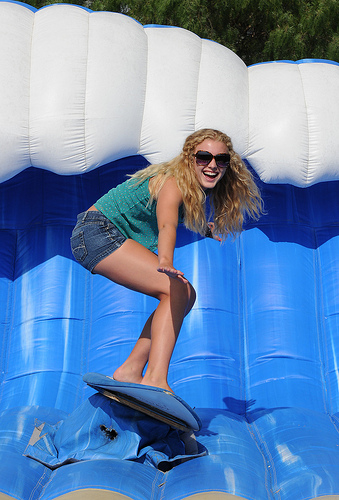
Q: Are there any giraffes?
A: No, there are no giraffes.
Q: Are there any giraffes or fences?
A: No, there are no giraffes or fences.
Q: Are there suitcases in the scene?
A: No, there are no suitcases.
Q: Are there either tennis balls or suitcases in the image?
A: No, there are no suitcases or tennis balls.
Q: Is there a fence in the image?
A: No, there are no fences.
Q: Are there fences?
A: No, there are no fences.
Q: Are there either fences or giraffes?
A: No, there are no fences or giraffes.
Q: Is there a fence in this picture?
A: No, there are no fences.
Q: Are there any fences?
A: No, there are no fences.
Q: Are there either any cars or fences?
A: No, there are no fences or cars.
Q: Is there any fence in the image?
A: No, there are no fences.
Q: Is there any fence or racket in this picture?
A: No, there are no fences or rackets.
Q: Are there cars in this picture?
A: No, there are no cars.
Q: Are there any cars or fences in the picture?
A: No, there are no cars or fences.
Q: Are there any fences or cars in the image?
A: No, there are no cars or fences.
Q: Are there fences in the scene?
A: No, there are no fences.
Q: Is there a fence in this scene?
A: No, there are no fences.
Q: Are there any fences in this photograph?
A: No, there are no fences.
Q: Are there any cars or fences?
A: No, there are no fences or cars.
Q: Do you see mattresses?
A: No, there are no mattresses.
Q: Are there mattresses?
A: No, there are no mattresses.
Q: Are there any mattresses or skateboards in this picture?
A: No, there are no mattresses or skateboards.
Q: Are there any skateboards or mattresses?
A: No, there are no mattresses or skateboards.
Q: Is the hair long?
A: Yes, the hair is long.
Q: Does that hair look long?
A: Yes, the hair is long.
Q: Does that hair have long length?
A: Yes, the hair is long.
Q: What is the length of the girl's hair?
A: The hair is long.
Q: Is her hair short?
A: No, the hair is long.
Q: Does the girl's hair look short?
A: No, the hair is long.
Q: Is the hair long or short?
A: The hair is long.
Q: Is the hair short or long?
A: The hair is long.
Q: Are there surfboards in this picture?
A: Yes, there is a surfboard.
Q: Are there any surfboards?
A: Yes, there is a surfboard.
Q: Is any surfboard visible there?
A: Yes, there is a surfboard.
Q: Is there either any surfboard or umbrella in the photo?
A: Yes, there is a surfboard.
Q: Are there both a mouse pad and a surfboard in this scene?
A: No, there is a surfboard but no mouse pads.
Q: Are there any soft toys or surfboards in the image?
A: Yes, there is a soft surfboard.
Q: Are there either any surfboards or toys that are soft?
A: Yes, the surfboard is soft.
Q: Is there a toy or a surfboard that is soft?
A: Yes, the surfboard is soft.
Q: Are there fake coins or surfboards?
A: Yes, there is a fake surfboard.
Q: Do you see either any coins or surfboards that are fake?
A: Yes, the surfboard is fake.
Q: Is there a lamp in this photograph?
A: No, there are no lamps.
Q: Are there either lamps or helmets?
A: No, there are no lamps or helmets.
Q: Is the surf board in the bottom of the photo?
A: Yes, the surf board is in the bottom of the image.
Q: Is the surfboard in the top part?
A: No, the surfboard is in the bottom of the image.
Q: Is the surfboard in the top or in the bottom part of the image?
A: The surfboard is in the bottom of the image.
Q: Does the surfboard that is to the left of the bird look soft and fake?
A: Yes, the surfboard is soft and fake.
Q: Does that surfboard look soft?
A: Yes, the surfboard is soft.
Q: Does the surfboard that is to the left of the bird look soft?
A: Yes, the surfboard is soft.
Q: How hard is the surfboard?
A: The surfboard is soft.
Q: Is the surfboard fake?
A: Yes, the surfboard is fake.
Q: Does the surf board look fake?
A: Yes, the surf board is fake.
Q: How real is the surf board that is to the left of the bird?
A: The surfboard is fake.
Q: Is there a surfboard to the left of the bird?
A: Yes, there is a surfboard to the left of the bird.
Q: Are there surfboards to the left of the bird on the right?
A: Yes, there is a surfboard to the left of the bird.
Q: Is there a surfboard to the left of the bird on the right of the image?
A: Yes, there is a surfboard to the left of the bird.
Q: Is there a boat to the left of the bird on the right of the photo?
A: No, there is a surfboard to the left of the bird.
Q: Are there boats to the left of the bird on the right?
A: No, there is a surfboard to the left of the bird.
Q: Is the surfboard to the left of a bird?
A: Yes, the surfboard is to the left of a bird.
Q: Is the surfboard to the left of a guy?
A: No, the surfboard is to the left of a bird.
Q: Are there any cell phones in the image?
A: No, there are no cell phones.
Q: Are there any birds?
A: Yes, there is a bird.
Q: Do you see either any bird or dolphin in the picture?
A: Yes, there is a bird.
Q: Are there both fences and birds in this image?
A: No, there is a bird but no fences.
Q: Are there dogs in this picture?
A: No, there are no dogs.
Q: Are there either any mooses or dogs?
A: No, there are no dogs or mooses.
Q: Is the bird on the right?
A: Yes, the bird is on the right of the image.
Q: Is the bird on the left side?
A: No, the bird is on the right of the image.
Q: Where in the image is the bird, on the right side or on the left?
A: The bird is on the right of the image.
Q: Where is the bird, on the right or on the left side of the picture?
A: The bird is on the right of the image.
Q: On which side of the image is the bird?
A: The bird is on the right of the image.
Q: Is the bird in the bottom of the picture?
A: Yes, the bird is in the bottom of the image.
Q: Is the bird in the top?
A: No, the bird is in the bottom of the image.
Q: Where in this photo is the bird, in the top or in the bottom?
A: The bird is in the bottom of the image.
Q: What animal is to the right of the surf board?
A: The animal is a bird.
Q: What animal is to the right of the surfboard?
A: The animal is a bird.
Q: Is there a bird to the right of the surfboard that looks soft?
A: Yes, there is a bird to the right of the surfboard.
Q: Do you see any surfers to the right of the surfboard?
A: No, there is a bird to the right of the surfboard.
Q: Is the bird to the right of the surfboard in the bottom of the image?
A: Yes, the bird is to the right of the surfboard.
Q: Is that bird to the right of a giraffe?
A: No, the bird is to the right of the surfboard.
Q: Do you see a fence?
A: No, there are no fences.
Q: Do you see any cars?
A: No, there are no cars.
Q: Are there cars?
A: No, there are no cars.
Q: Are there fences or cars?
A: No, there are no cars or fences.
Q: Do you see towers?
A: No, there are no towers.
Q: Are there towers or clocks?
A: No, there are no towers or clocks.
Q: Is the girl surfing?
A: Yes, the girl is surfing.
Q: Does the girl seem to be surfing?
A: Yes, the girl is surfing.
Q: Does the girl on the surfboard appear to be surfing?
A: Yes, the girl is surfing.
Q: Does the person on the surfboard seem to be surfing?
A: Yes, the girl is surfing.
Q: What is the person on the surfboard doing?
A: The girl is surfing.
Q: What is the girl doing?
A: The girl is surfing.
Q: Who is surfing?
A: The girl is surfing.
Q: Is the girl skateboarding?
A: No, the girl is surfing.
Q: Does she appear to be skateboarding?
A: No, the girl is surfing.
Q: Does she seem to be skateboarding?
A: No, the girl is surfing.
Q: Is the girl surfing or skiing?
A: The girl is surfing.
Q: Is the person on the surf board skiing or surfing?
A: The girl is surfing.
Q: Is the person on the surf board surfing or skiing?
A: The girl is surfing.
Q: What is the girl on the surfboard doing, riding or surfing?
A: The girl is surfing.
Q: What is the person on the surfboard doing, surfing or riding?
A: The girl is surfing.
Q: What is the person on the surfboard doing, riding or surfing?
A: The girl is surfing.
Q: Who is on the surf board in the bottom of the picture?
A: The girl is on the surfboard.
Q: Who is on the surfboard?
A: The girl is on the surfboard.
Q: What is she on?
A: The girl is on the surfboard.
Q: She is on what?
A: The girl is on the surfboard.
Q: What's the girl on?
A: The girl is on the surfboard.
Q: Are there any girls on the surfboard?
A: Yes, there is a girl on the surfboard.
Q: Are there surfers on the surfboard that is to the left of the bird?
A: No, there is a girl on the surfboard.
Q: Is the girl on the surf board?
A: Yes, the girl is on the surf board.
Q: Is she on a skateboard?
A: No, the girl is on the surf board.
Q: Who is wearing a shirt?
A: The girl is wearing a shirt.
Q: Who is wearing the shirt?
A: The girl is wearing a shirt.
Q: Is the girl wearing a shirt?
A: Yes, the girl is wearing a shirt.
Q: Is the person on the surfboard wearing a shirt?
A: Yes, the girl is wearing a shirt.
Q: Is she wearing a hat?
A: No, the girl is wearing a shirt.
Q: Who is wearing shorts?
A: The girl is wearing shorts.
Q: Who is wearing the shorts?
A: The girl is wearing shorts.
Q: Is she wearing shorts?
A: Yes, the girl is wearing shorts.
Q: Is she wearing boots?
A: No, the girl is wearing shorts.